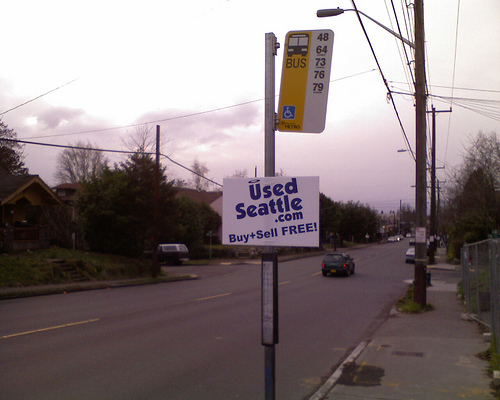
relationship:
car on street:
[320, 246, 360, 287] [183, 336, 240, 369]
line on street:
[20, 309, 112, 338] [183, 336, 240, 369]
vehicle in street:
[150, 229, 194, 273] [0, 234, 411, 400]